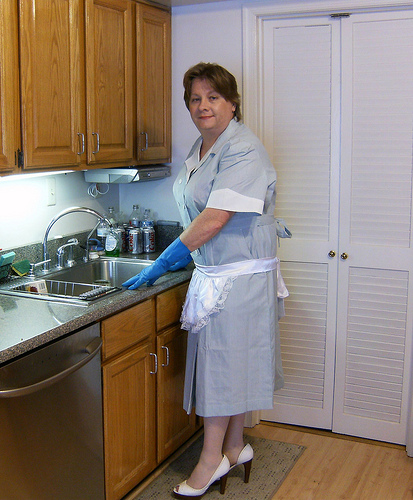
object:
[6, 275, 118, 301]
drain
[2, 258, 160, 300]
sink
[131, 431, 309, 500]
mat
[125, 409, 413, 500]
floor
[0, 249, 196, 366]
counter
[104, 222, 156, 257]
bottles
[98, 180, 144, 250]
corner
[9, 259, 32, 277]
sponge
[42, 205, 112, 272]
facuet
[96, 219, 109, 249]
bottle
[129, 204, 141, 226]
bottle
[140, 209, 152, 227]
bottle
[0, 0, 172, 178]
cabinets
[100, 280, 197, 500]
cabinets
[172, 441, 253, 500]
heels stiletto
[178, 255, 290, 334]
apron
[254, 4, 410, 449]
closet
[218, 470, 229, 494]
heel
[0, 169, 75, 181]
light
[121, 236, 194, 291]
glove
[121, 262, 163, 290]
hands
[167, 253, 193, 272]
hands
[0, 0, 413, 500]
kitchen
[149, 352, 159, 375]
handle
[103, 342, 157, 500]
cabinet door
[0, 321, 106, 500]
cabinet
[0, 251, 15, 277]
sponge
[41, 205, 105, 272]
faucets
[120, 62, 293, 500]
lady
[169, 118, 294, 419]
maid outfit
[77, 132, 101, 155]
handles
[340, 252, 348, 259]
knob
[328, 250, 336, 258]
knob